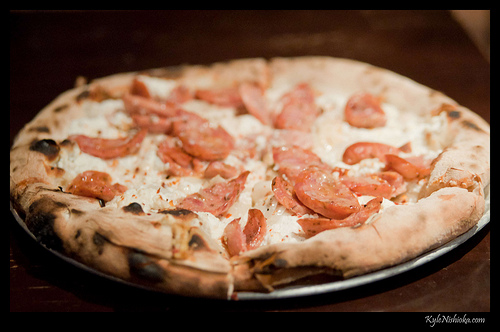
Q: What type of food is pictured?
A: Pizza.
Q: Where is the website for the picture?
A: Bottom right.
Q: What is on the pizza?
A: Meat and cheese.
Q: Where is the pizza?
A: On dish.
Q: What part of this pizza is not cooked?
A: Pizza is cooked fully.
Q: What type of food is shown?
A: Pizza.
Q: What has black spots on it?
A: Pizza crust.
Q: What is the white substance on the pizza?
A: Cheese.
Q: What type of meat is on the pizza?
A: Pepperoni.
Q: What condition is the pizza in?
A: Baked and cut.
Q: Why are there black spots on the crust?
A: Burnt.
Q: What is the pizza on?
A: Plate.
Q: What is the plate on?
A: Table.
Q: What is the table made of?
A: Wood.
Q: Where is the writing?
A: Bottom right side.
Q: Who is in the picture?
A: No one.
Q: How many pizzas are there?
A: One.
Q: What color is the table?
A: Brown.